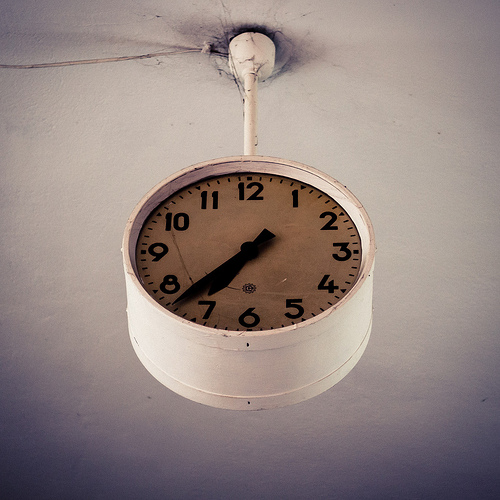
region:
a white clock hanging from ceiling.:
[87, 2, 404, 421]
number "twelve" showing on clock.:
[233, 176, 272, 208]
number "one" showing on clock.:
[284, 179, 310, 214]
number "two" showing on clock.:
[315, 210, 338, 232]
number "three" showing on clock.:
[326, 235, 346, 270]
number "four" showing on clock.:
[310, 265, 340, 295]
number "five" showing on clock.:
[275, 287, 305, 317]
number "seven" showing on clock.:
[195, 295, 220, 320]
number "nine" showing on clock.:
[140, 236, 172, 266]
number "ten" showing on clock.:
[160, 210, 192, 235]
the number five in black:
[274, 283, 319, 329]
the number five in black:
[279, 290, 307, 326]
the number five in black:
[279, 284, 313, 336]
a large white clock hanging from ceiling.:
[94, 84, 411, 422]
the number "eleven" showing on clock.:
[194, 181, 225, 219]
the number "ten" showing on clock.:
[155, 207, 205, 235]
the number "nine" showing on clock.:
[145, 237, 173, 264]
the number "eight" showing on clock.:
[155, 263, 183, 302]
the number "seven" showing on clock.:
[187, 289, 224, 326]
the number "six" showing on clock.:
[227, 298, 268, 330]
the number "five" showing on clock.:
[271, 283, 308, 329]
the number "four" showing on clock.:
[312, 263, 346, 310]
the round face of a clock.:
[132, 163, 368, 338]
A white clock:
[121, 24, 405, 407]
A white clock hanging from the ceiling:
[129, 20, 381, 443]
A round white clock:
[80, 137, 399, 424]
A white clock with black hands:
[116, 158, 398, 391]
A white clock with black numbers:
[124, 157, 389, 419]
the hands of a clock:
[158, 229, 288, 308]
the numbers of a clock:
[180, 185, 342, 245]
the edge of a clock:
[309, 165, 387, 345]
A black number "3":
[319, 229, 357, 268]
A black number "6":
[237, 297, 264, 336]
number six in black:
[228, 296, 268, 339]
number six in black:
[229, 303, 260, 330]